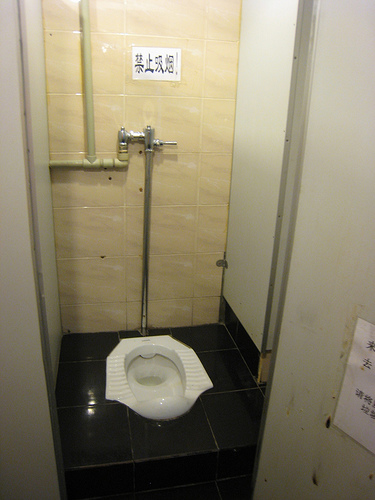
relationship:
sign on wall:
[320, 306, 370, 426] [288, 297, 322, 378]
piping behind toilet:
[134, 169, 157, 329] [94, 331, 216, 433]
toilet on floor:
[92, 334, 222, 421] [55, 318, 270, 498]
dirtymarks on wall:
[310, 413, 336, 490] [252, 0, 372, 498]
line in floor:
[187, 394, 230, 458] [57, 331, 307, 447]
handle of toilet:
[153, 138, 182, 149] [100, 116, 216, 421]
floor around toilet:
[66, 329, 256, 497] [104, 334, 214, 421]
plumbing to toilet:
[46, 1, 178, 333] [104, 334, 214, 421]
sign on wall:
[132, 44, 181, 82] [42, 0, 241, 334]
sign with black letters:
[132, 44, 181, 82] [134, 53, 173, 73]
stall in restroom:
[104, 126, 212, 419] [31, 2, 373, 472]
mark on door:
[321, 409, 331, 435] [261, 1, 369, 490]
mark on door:
[280, 386, 298, 423] [261, 1, 369, 490]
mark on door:
[309, 468, 319, 488] [261, 1, 369, 490]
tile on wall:
[80, 259, 125, 302] [36, 0, 220, 313]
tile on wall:
[155, 206, 197, 253] [36, 0, 220, 313]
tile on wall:
[199, 155, 227, 205] [36, 0, 220, 313]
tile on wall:
[78, 93, 124, 152] [36, 0, 220, 313]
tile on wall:
[202, 95, 228, 152] [36, 0, 220, 313]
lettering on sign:
[138, 52, 207, 79] [112, 40, 196, 97]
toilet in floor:
[103, 334, 215, 421] [56, 322, 265, 498]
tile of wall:
[200, 35, 241, 101] [42, 0, 241, 334]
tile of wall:
[199, 95, 235, 156] [42, 0, 241, 334]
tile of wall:
[197, 155, 232, 205] [42, 0, 241, 334]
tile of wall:
[190, 200, 231, 254] [42, 0, 241, 334]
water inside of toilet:
[129, 363, 176, 392] [104, 334, 214, 421]